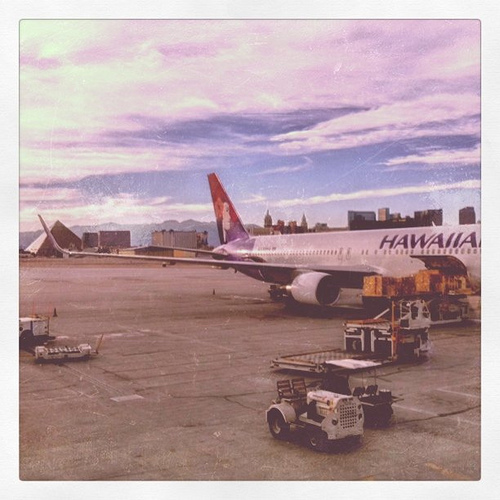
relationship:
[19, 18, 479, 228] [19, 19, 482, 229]
clouds in sky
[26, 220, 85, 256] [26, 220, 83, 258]
pyramid in background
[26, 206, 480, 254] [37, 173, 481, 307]
city behind plane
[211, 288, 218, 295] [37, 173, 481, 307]
cone behind plane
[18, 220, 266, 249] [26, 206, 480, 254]
mountain behind city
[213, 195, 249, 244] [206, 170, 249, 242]
logo on tail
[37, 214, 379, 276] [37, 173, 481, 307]
wing on plane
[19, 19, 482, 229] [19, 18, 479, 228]
sky has clouds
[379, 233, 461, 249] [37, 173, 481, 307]
hawaii on plane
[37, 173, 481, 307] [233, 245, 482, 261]
plane has windows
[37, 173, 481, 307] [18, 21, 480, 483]
plane at airport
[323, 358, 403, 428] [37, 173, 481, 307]
golf cart near plane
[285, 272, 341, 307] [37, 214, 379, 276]
engine below wing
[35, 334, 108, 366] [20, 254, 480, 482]
trailer on tarmac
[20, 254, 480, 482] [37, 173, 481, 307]
tarmac under plane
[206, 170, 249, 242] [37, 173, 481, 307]
tail on plane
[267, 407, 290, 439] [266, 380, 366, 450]
wheel under truck